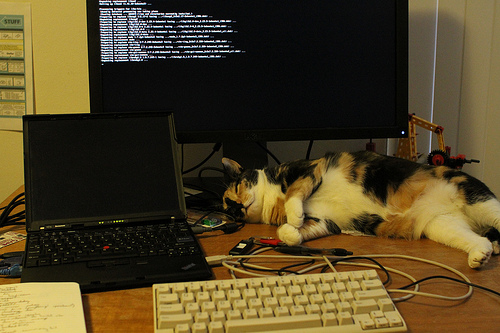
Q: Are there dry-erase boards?
A: No, there are no dry-erase boards.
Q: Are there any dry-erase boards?
A: No, there are no dry-erase boards.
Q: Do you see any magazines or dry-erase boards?
A: No, there are no dry-erase boards or magazines.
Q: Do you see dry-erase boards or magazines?
A: No, there are no dry-erase boards or magazines.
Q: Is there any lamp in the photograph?
A: No, there are no lamps.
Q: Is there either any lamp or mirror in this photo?
A: No, there are no lamps or mirrors.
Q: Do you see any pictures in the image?
A: No, there are no pictures.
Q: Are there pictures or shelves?
A: No, there are no pictures or shelves.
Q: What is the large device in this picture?
A: The device is a computer monitor.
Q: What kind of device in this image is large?
A: The device is a computer monitor.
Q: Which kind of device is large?
A: The device is a computer monitor.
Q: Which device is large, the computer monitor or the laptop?
A: The computer monitor is large.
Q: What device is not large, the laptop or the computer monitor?
A: The laptop is not large.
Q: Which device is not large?
A: The device is a laptop.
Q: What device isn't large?
A: The device is a laptop.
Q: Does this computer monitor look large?
A: Yes, the computer monitor is large.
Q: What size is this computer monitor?
A: The computer monitor is large.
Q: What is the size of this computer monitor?
A: The computer monitor is large.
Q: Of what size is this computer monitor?
A: The computer monitor is large.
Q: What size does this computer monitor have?
A: The computer monitor has large size.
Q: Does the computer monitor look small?
A: No, the computer monitor is large.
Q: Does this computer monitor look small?
A: No, the computer monitor is large.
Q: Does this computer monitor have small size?
A: No, the computer monitor is large.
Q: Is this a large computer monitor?
A: Yes, this is a large computer monitor.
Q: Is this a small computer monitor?
A: No, this is a large computer monitor.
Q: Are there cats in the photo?
A: Yes, there is a cat.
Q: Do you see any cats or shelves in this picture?
A: Yes, there is a cat.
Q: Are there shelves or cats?
A: Yes, there is a cat.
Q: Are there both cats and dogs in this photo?
A: No, there is a cat but no dogs.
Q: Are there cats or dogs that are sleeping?
A: Yes, the cat is sleeping.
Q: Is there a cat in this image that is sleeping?
A: Yes, there is a cat that is sleeping.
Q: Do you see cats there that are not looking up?
A: Yes, there is a cat that is sleeping .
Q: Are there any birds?
A: No, there are no birds.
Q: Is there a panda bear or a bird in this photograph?
A: No, there are no birds or panda bears.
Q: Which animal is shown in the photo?
A: The animal is a cat.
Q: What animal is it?
A: The animal is a cat.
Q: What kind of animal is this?
A: This is a cat.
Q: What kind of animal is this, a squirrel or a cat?
A: This is a cat.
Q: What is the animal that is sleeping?
A: The animal is a cat.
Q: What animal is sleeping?
A: The animal is a cat.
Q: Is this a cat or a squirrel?
A: This is a cat.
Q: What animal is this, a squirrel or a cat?
A: This is a cat.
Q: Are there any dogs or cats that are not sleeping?
A: No, there is a cat but it is sleeping.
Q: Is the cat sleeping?
A: Yes, the cat is sleeping.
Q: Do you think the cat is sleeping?
A: Yes, the cat is sleeping.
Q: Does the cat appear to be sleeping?
A: Yes, the cat is sleeping.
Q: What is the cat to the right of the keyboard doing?
A: The cat is sleeping.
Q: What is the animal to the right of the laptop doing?
A: The cat is sleeping.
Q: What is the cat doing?
A: The cat is sleeping.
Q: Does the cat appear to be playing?
A: No, the cat is sleeping.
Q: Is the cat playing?
A: No, the cat is sleeping.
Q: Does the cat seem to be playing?
A: No, the cat is sleeping.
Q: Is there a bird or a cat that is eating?
A: No, there is a cat but it is sleeping.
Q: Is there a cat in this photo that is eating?
A: No, there is a cat but it is sleeping.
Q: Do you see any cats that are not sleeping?
A: No, there is a cat but it is sleeping.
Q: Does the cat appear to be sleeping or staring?
A: The cat is sleeping.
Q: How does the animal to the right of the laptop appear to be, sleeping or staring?
A: The cat is sleeping.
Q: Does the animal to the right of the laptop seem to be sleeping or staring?
A: The cat is sleeping.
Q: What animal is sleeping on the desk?
A: The cat is sleeping on the desk.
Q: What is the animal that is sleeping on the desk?
A: The animal is a cat.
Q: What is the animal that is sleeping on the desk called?
A: The animal is a cat.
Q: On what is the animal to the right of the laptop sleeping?
A: The cat is sleeping on the desk.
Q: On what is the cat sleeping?
A: The cat is sleeping on the desk.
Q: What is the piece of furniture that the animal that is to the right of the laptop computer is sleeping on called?
A: The piece of furniture is a desk.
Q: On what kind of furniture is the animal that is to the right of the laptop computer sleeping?
A: The cat is sleeping on the desk.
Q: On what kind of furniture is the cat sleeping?
A: The cat is sleeping on the desk.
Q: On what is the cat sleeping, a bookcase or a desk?
A: The cat is sleeping on a desk.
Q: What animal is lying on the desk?
A: The cat is lying on the desk.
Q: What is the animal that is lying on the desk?
A: The animal is a cat.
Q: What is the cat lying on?
A: The cat is lying on the desk.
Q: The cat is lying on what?
A: The cat is lying on the desk.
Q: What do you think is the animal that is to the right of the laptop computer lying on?
A: The cat is lying on the desk.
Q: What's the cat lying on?
A: The cat is lying on the desk.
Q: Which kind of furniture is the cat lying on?
A: The cat is lying on the desk.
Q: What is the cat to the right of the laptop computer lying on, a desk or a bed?
A: The cat is lying on a desk.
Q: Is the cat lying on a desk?
A: Yes, the cat is lying on a desk.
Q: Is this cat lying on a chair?
A: No, the cat is lying on a desk.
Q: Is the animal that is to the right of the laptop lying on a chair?
A: No, the cat is lying on a desk.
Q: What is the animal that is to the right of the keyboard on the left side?
A: The animal is a cat.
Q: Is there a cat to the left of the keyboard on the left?
A: No, the cat is to the right of the keyboard.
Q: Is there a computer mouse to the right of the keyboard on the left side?
A: No, there is a cat to the right of the keyboard.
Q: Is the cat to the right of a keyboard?
A: Yes, the cat is to the right of a keyboard.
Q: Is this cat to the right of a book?
A: No, the cat is to the right of a keyboard.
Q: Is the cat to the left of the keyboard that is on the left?
A: No, the cat is to the right of the keyboard.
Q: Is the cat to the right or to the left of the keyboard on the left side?
A: The cat is to the right of the keyboard.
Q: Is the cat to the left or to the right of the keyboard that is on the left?
A: The cat is to the right of the keyboard.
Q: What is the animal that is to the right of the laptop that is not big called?
A: The animal is a cat.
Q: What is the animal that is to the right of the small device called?
A: The animal is a cat.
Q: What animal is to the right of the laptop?
A: The animal is a cat.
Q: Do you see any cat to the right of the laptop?
A: Yes, there is a cat to the right of the laptop.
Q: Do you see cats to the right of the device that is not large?
A: Yes, there is a cat to the right of the laptop.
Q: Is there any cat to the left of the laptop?
A: No, the cat is to the right of the laptop.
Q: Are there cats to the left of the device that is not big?
A: No, the cat is to the right of the laptop.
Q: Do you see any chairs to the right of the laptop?
A: No, there is a cat to the right of the laptop.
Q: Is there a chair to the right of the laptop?
A: No, there is a cat to the right of the laptop.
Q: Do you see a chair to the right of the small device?
A: No, there is a cat to the right of the laptop.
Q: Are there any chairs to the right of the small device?
A: No, there is a cat to the right of the laptop.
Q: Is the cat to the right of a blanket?
A: No, the cat is to the right of the laptop.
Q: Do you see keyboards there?
A: Yes, there is a keyboard.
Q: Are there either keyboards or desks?
A: Yes, there is a keyboard.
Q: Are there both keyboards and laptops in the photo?
A: Yes, there are both a keyboard and a laptop.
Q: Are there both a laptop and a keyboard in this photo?
A: Yes, there are both a keyboard and a laptop.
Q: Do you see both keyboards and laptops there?
A: Yes, there are both a keyboard and a laptop.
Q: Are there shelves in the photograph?
A: No, there are no shelves.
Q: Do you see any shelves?
A: No, there are no shelves.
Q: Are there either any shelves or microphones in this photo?
A: No, there are no shelves or microphones.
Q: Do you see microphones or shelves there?
A: No, there are no shelves or microphones.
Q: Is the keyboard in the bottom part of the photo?
A: Yes, the keyboard is in the bottom of the image.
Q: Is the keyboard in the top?
A: No, the keyboard is in the bottom of the image.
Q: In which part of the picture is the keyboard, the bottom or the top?
A: The keyboard is in the bottom of the image.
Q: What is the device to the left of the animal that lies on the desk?
A: The device is a keyboard.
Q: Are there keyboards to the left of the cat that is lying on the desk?
A: Yes, there is a keyboard to the left of the cat.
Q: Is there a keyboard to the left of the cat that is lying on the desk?
A: Yes, there is a keyboard to the left of the cat.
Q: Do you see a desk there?
A: Yes, there is a desk.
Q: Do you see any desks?
A: Yes, there is a desk.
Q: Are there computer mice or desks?
A: Yes, there is a desk.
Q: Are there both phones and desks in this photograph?
A: No, there is a desk but no phones.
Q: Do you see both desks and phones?
A: No, there is a desk but no phones.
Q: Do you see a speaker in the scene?
A: No, there are no speakers.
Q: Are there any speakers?
A: No, there are no speakers.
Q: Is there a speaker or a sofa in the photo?
A: No, there are no speakers or sofas.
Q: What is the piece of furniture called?
A: The piece of furniture is a desk.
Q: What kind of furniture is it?
A: The piece of furniture is a desk.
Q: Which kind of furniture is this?
A: That is a desk.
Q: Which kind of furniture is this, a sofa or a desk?
A: That is a desk.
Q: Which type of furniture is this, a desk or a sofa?
A: That is a desk.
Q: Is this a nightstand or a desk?
A: This is a desk.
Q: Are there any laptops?
A: Yes, there is a laptop.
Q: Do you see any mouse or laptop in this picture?
A: Yes, there is a laptop.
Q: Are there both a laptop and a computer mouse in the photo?
A: No, there is a laptop but no computer mice.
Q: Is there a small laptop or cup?
A: Yes, there is a small laptop.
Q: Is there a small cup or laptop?
A: Yes, there is a small laptop.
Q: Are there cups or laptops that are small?
A: Yes, the laptop is small.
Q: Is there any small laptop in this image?
A: Yes, there is a small laptop.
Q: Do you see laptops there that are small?
A: Yes, there is a laptop that is small.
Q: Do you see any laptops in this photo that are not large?
A: Yes, there is a small laptop.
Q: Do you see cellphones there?
A: No, there are no cellphones.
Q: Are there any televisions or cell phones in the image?
A: No, there are no cell phones or televisions.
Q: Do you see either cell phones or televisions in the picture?
A: No, there are no cell phones or televisions.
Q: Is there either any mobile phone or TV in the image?
A: No, there are no cell phones or televisions.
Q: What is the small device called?
A: The device is a laptop.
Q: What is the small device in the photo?
A: The device is a laptop.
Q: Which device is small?
A: The device is a laptop.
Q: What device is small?
A: The device is a laptop.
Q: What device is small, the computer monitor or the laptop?
A: The laptop is small.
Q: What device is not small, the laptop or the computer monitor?
A: The computer monitor is not small.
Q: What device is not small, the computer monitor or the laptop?
A: The computer monitor is not small.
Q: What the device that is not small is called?
A: The device is a computer monitor.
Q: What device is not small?
A: The device is a computer monitor.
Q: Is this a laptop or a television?
A: This is a laptop.